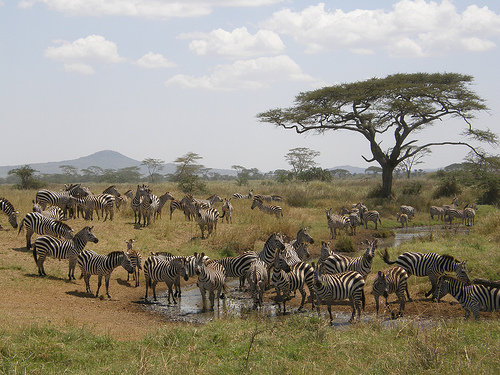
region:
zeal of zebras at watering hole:
[3, 178, 498, 339]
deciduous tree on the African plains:
[250, 59, 495, 206]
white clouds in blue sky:
[3, 2, 497, 74]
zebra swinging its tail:
[373, 242, 473, 309]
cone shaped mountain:
[10, 142, 176, 180]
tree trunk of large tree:
[365, 137, 414, 198]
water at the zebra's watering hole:
[132, 217, 494, 337]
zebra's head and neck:
[70, 222, 100, 249]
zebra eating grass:
[1, 192, 22, 232]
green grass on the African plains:
[8, 322, 496, 372]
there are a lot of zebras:
[6, 159, 496, 337]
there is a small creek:
[151, 199, 490, 340]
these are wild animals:
[24, 178, 494, 340]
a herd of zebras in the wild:
[9, 165, 496, 340]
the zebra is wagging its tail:
[369, 239, 487, 305]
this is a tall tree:
[252, 60, 497, 217]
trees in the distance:
[6, 140, 331, 199]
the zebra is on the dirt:
[56, 232, 151, 307]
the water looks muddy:
[162, 284, 307, 327]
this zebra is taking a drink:
[240, 255, 280, 317]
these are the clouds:
[6, 3, 498, 90]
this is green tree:
[251, 70, 498, 206]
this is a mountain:
[57, 143, 145, 175]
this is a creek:
[140, 214, 499, 335]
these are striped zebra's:
[0, 178, 499, 338]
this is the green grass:
[2, 316, 498, 371]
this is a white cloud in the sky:
[36, 28, 125, 75]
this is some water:
[140, 278, 499, 342]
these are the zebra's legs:
[77, 273, 93, 300]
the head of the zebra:
[269, 230, 287, 255]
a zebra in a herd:
[434, 276, 499, 323]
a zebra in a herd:
[370, 267, 407, 313]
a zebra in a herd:
[376, 245, 467, 300]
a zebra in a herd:
[16, 210, 71, 250]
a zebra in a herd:
[27, 225, 97, 278]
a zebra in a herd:
[73, 248, 129, 296]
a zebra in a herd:
[143, 253, 188, 308]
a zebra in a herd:
[188, 251, 228, 311]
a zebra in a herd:
[323, 207, 353, 238]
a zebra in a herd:
[191, 204, 219, 239]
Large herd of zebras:
[2, 179, 497, 324]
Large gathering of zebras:
[1, 182, 498, 330]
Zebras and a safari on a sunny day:
[1, 0, 498, 373]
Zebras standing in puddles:
[140, 245, 412, 322]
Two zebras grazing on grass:
[0, 197, 76, 254]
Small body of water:
[136, 218, 471, 340]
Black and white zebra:
[310, 258, 367, 326]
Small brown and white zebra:
[123, 233, 141, 288]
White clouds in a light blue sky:
[1, 0, 498, 170]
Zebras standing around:
[0, 179, 498, 328]